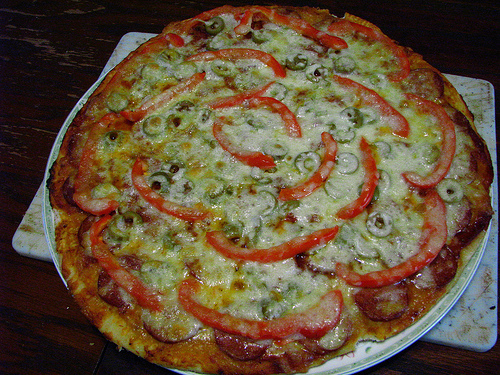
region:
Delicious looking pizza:
[50, 2, 494, 373]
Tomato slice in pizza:
[179, 278, 345, 340]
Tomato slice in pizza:
[128, 154, 208, 219]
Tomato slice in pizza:
[337, 132, 380, 220]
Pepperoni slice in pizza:
[356, 279, 408, 321]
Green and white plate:
[300, 210, 493, 374]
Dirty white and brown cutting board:
[12, 15, 497, 341]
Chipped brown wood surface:
[2, 2, 498, 371]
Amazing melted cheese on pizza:
[61, 16, 473, 351]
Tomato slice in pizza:
[188, 48, 290, 80]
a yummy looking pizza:
[33, 25, 489, 358]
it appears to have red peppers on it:
[158, 50, 401, 287]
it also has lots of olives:
[160, 92, 366, 236]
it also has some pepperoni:
[216, 275, 427, 362]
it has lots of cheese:
[241, 108, 391, 230]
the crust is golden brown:
[67, 235, 205, 372]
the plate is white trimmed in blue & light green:
[114, 13, 496, 373]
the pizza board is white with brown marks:
[5, 10, 494, 365]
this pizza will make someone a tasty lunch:
[77, 20, 495, 367]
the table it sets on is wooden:
[7, 87, 56, 181]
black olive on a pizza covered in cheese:
[362, 208, 394, 239]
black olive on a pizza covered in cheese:
[335, 149, 358, 176]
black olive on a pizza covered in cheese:
[437, 177, 467, 204]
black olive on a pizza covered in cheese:
[291, 149, 323, 173]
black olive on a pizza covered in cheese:
[148, 167, 171, 194]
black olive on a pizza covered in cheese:
[302, 62, 328, 87]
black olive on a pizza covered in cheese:
[332, 52, 355, 76]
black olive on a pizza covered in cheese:
[285, 48, 307, 74]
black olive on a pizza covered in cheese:
[206, 15, 227, 37]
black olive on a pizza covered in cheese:
[141, 109, 169, 141]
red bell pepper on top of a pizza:
[332, 133, 380, 222]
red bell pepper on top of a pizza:
[332, 185, 454, 294]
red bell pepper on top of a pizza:
[172, 277, 347, 342]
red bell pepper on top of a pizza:
[84, 213, 161, 315]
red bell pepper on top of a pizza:
[69, 110, 135, 217]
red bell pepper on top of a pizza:
[115, 67, 210, 128]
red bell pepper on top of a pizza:
[182, 47, 286, 78]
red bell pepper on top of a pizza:
[232, 0, 346, 58]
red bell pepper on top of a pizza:
[325, 13, 415, 84]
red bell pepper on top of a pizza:
[402, 85, 461, 190]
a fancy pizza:
[36, 15, 497, 353]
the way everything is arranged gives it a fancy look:
[8, 4, 456, 374]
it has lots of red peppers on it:
[138, 84, 417, 282]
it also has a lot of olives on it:
[158, 160, 410, 256]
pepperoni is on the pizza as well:
[211, 240, 466, 371]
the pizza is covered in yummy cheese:
[157, 135, 369, 232]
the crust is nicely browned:
[51, 98, 163, 356]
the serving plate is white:
[183, 40, 497, 370]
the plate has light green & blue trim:
[334, 253, 499, 373]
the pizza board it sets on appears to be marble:
[32, 63, 495, 366]